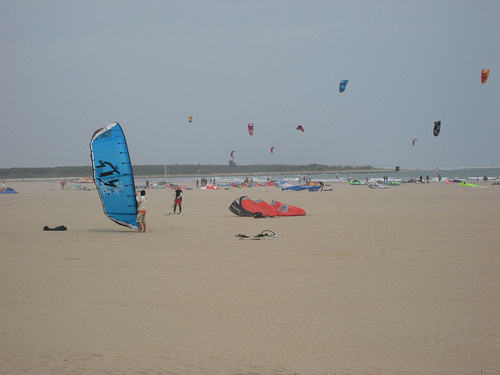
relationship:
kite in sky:
[337, 76, 348, 93] [1, 0, 500, 169]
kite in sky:
[478, 67, 490, 84] [1, 0, 500, 169]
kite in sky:
[430, 118, 442, 137] [1, 0, 500, 169]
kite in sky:
[410, 136, 419, 148] [1, 0, 500, 169]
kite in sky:
[294, 122, 308, 132] [1, 0, 500, 169]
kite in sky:
[246, 121, 255, 136] [1, 0, 500, 169]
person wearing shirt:
[134, 186, 149, 233] [134, 195, 148, 211]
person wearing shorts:
[134, 186, 149, 233] [136, 211, 147, 223]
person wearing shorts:
[172, 185, 183, 215] [174, 196, 182, 205]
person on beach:
[134, 186, 149, 233] [3, 181, 499, 370]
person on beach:
[172, 185, 183, 215] [3, 181, 499, 370]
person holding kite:
[134, 186, 149, 233] [88, 120, 139, 230]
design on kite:
[95, 157, 120, 189] [88, 120, 139, 230]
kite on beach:
[227, 192, 306, 218] [3, 181, 499, 370]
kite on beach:
[278, 183, 320, 192] [3, 181, 499, 370]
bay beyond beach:
[103, 169, 499, 177] [3, 181, 499, 370]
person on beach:
[423, 172, 431, 184] [3, 181, 499, 370]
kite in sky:
[185, 113, 197, 124] [1, 0, 500, 169]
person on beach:
[418, 172, 424, 182] [3, 181, 499, 370]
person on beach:
[142, 178, 151, 190] [3, 181, 499, 370]